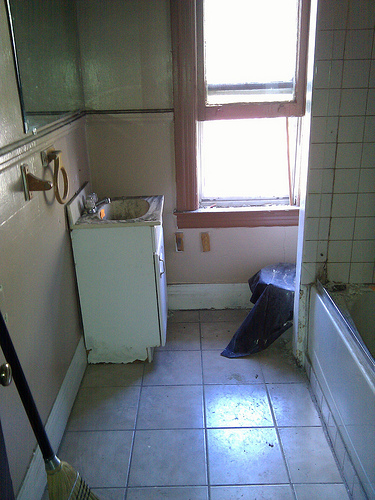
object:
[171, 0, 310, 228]
window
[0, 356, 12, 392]
handle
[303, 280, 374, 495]
tub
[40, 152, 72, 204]
ring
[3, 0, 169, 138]
mirror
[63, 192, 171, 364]
vanity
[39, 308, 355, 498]
floor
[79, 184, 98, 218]
knobs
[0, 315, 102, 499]
broom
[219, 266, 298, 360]
cover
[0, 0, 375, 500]
toilet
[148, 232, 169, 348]
door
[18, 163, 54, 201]
hook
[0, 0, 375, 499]
wall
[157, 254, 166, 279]
handle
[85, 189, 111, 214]
faucet